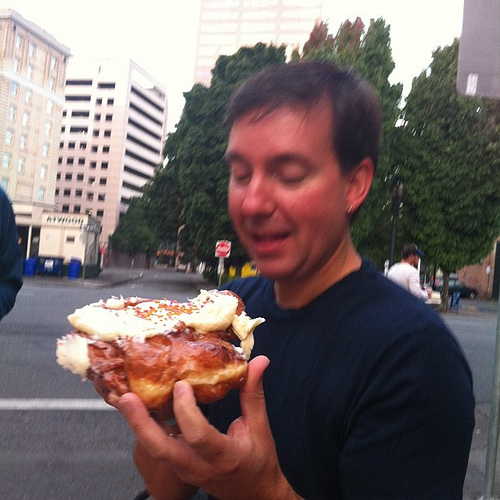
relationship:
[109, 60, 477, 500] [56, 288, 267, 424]
man holding food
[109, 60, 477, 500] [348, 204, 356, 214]
man wearing earring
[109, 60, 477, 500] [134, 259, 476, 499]
man wearing shirt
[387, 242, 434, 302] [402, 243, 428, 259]
man wearing cap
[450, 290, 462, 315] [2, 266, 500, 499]
mailbox near street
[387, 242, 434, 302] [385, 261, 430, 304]
man wearing shirt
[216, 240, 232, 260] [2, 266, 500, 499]
stop sign on top of street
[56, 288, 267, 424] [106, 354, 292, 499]
food in hand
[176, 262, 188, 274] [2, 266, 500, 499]
car on top of street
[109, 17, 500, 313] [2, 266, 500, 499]
trees near street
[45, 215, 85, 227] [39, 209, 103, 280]
sign on building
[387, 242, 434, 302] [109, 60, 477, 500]
man behind man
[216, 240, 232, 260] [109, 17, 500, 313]
stop sign near trees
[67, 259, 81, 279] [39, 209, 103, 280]
trash bin next to building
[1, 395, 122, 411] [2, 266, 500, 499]
traffic line on top of street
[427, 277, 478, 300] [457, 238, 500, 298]
car near building